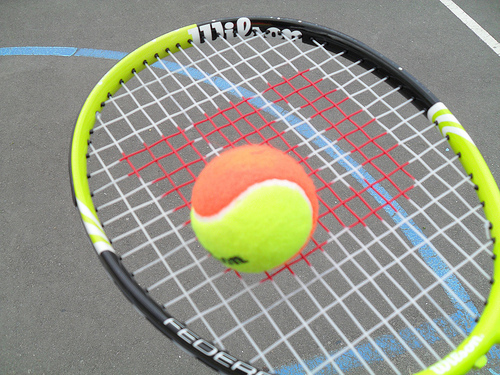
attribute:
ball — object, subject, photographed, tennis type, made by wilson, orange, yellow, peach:
[190, 144, 321, 276]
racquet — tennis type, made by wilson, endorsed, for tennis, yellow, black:
[71, 17, 496, 371]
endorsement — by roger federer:
[160, 320, 274, 373]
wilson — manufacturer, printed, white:
[187, 17, 303, 49]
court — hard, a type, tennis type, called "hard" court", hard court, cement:
[5, 5, 493, 368]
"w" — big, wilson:
[125, 70, 419, 289]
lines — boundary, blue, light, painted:
[3, 45, 497, 368]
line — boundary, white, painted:
[442, 5, 498, 57]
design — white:
[66, 200, 117, 255]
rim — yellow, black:
[72, 18, 495, 370]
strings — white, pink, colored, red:
[86, 25, 497, 369]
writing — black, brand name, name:
[213, 252, 251, 269]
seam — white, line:
[191, 177, 316, 230]